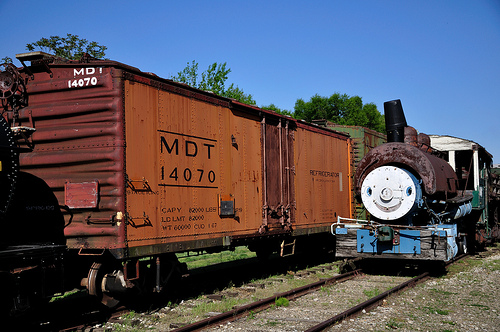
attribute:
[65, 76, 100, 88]
number — white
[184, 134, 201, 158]
letter — black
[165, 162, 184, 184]
number — brown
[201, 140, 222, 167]
letter — brown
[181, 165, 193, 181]
number — black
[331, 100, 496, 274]
train — old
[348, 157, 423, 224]
face — smiley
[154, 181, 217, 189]
line — black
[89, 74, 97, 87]
number — white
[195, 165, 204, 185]
number — brown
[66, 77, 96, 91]
number — white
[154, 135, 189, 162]
letter — black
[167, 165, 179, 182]
number — black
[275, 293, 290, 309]
grass — green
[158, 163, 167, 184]
number — black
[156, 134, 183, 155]
letter — black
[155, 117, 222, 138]
line — black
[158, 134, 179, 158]
letter — brown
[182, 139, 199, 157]
letter — brown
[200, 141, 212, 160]
letter — brown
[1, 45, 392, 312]
train — old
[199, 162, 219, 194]
number — black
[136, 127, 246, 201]
number — brown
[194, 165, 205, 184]
number — black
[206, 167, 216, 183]
number — brown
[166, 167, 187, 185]
number — brown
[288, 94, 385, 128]
leaves — green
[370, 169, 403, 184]
paint — white